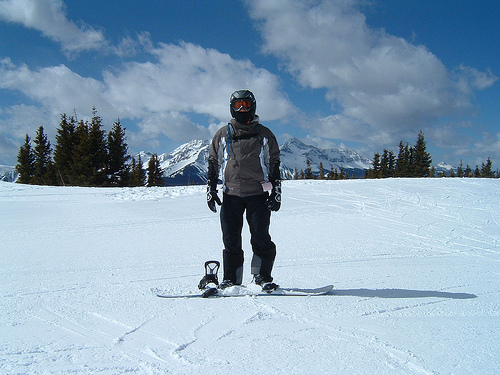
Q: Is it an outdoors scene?
A: Yes, it is outdoors.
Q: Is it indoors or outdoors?
A: It is outdoors.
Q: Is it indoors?
A: No, it is outdoors.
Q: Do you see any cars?
A: No, there are no cars.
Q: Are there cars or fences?
A: No, there are no cars or fences.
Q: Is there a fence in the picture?
A: No, there are no fences.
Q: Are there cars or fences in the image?
A: No, there are no fences or cars.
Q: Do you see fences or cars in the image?
A: No, there are no fences or cars.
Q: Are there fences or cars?
A: No, there are no fences or cars.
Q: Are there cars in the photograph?
A: No, there are no cars.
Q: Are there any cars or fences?
A: No, there are no cars or fences.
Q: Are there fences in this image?
A: No, there are no fences.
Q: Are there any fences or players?
A: No, there are no fences or players.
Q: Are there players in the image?
A: No, there are no players.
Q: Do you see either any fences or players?
A: No, there are no players or fences.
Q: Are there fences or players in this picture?
A: No, there are no players or fences.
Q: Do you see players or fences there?
A: No, there are no players or fences.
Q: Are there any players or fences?
A: No, there are no players or fences.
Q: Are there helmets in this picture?
A: Yes, there is a helmet.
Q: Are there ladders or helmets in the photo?
A: Yes, there is a helmet.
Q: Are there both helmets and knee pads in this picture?
A: No, there is a helmet but no knee pads.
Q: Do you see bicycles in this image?
A: No, there are no bicycles.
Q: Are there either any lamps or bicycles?
A: No, there are no bicycles or lamps.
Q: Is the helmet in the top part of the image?
A: Yes, the helmet is in the top of the image.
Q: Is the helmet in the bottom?
A: No, the helmet is in the top of the image.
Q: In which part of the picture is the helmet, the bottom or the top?
A: The helmet is in the top of the image.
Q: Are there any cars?
A: No, there are no cars.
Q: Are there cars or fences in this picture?
A: No, there are no cars or fences.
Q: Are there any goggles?
A: Yes, there are goggles.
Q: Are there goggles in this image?
A: Yes, there are goggles.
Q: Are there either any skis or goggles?
A: Yes, there are goggles.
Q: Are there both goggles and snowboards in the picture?
A: Yes, there are both goggles and a snowboard.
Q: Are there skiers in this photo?
A: No, there are no skiers.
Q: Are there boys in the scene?
A: No, there are no boys.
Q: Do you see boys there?
A: No, there are no boys.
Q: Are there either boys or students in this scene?
A: No, there are no boys or students.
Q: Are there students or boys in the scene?
A: No, there are no boys or students.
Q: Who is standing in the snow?
A: The man is standing in the snow.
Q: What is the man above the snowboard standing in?
A: The man is standing in the snow.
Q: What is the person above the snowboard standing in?
A: The man is standing in the snow.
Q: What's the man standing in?
A: The man is standing in the snow.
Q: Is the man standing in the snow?
A: Yes, the man is standing in the snow.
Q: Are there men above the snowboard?
A: Yes, there is a man above the snowboard.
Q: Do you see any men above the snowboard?
A: Yes, there is a man above the snowboard.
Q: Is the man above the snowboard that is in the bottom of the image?
A: Yes, the man is above the snowboard.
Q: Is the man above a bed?
A: No, the man is above the snowboard.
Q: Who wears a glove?
A: The man wears a glove.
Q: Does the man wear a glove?
A: Yes, the man wears a glove.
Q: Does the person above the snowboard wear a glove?
A: Yes, the man wears a glove.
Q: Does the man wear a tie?
A: No, the man wears a glove.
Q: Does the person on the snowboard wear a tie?
A: No, the man wears a glove.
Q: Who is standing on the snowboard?
A: The man is standing on the snowboard.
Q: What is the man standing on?
A: The man is standing on the snowboard.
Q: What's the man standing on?
A: The man is standing on the snowboard.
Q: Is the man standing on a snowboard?
A: Yes, the man is standing on a snowboard.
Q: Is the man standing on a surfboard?
A: No, the man is standing on a snowboard.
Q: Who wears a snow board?
A: The man wears a snow board.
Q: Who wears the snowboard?
A: The man wears a snow board.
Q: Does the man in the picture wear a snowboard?
A: Yes, the man wears a snowboard.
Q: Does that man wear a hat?
A: No, the man wears a snowboard.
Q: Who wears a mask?
A: The man wears a mask.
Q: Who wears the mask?
A: The man wears a mask.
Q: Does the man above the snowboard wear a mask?
A: Yes, the man wears a mask.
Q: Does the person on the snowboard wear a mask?
A: Yes, the man wears a mask.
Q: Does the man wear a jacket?
A: No, the man wears a mask.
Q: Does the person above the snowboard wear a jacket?
A: No, the man wears a mask.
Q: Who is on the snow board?
A: The man is on the snow board.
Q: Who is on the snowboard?
A: The man is on the snow board.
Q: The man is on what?
A: The man is on the snowboard.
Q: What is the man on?
A: The man is on the snowboard.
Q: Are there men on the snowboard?
A: Yes, there is a man on the snowboard.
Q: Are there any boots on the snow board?
A: No, there is a man on the snow board.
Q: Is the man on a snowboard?
A: Yes, the man is on a snowboard.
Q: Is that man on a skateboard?
A: No, the man is on a snowboard.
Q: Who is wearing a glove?
A: The man is wearing a glove.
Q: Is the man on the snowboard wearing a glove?
A: Yes, the man is wearing a glove.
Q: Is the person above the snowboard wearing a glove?
A: Yes, the man is wearing a glove.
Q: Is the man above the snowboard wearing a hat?
A: No, the man is wearing a glove.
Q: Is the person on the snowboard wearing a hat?
A: No, the man is wearing a glove.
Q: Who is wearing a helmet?
A: The man is wearing a helmet.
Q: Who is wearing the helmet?
A: The man is wearing a helmet.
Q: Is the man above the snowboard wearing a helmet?
A: Yes, the man is wearing a helmet.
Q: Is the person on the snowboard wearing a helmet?
A: Yes, the man is wearing a helmet.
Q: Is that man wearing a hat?
A: No, the man is wearing a helmet.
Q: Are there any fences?
A: No, there are no fences.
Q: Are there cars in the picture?
A: No, there are no cars.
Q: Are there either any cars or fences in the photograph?
A: No, there are no cars or fences.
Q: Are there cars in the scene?
A: No, there are no cars.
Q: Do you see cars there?
A: No, there are no cars.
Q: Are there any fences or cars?
A: No, there are no cars or fences.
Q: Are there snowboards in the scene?
A: Yes, there is a snowboard.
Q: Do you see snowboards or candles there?
A: Yes, there is a snowboard.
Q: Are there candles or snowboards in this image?
A: Yes, there is a snowboard.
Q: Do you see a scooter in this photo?
A: No, there are no scooters.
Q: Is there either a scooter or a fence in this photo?
A: No, there are no scooters or fences.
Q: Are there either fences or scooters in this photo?
A: No, there are no scooters or fences.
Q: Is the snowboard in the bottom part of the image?
A: Yes, the snowboard is in the bottom of the image.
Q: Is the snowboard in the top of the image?
A: No, the snowboard is in the bottom of the image.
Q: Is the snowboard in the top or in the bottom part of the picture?
A: The snowboard is in the bottom of the image.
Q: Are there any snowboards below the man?
A: Yes, there is a snowboard below the man.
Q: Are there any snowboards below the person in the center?
A: Yes, there is a snowboard below the man.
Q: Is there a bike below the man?
A: No, there is a snowboard below the man.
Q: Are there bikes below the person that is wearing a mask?
A: No, there is a snowboard below the man.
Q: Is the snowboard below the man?
A: Yes, the snowboard is below the man.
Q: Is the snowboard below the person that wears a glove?
A: Yes, the snowboard is below the man.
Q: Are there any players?
A: No, there are no players.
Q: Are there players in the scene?
A: No, there are no players.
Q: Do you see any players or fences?
A: No, there are no players or fences.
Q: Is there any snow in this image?
A: Yes, there is snow.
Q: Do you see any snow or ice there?
A: Yes, there is snow.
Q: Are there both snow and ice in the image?
A: No, there is snow but no ice.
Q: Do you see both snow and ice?
A: No, there is snow but no ice.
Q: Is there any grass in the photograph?
A: No, there is no grass.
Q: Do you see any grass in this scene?
A: No, there is no grass.